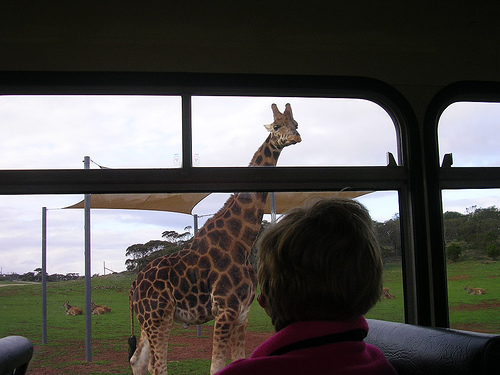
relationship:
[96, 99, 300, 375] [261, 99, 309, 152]
giraffe has head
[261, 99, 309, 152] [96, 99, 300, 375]
head of giraffe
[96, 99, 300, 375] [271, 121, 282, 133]
giraffe has eye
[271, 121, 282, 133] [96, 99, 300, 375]
eye of giraffe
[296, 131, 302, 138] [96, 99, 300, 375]
nose of giraffe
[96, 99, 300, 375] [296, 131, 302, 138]
giraffe has nose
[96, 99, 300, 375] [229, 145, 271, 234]
giraffe has neck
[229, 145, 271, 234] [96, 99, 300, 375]
neck of giraffe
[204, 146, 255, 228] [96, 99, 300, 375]
mane on giraffe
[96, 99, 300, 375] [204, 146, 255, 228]
giraffe has mane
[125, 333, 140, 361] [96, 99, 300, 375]
tail of giraffe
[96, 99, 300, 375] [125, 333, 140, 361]
giraffe has tail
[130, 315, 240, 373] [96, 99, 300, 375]
legs of giraffe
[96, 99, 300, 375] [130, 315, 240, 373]
giraffe has legs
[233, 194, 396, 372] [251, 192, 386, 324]
person has head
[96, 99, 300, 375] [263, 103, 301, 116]
giraffe has ears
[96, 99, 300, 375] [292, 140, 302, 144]
giraffe has mouth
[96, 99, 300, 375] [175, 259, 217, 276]
giraffe has spots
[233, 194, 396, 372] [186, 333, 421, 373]
person has jacket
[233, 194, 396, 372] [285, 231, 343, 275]
person has hair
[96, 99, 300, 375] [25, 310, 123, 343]
giraffe in grass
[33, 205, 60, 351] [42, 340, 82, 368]
pole in ground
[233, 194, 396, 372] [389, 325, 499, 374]
person in seat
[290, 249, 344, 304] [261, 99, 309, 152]
back of head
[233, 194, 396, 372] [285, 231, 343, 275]
woman has hair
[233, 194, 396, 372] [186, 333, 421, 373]
woman has jacket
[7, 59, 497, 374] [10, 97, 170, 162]
bus has window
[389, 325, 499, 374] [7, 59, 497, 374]
seat on bus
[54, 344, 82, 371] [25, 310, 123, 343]
patch on grass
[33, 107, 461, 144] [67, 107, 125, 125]
sky has clouds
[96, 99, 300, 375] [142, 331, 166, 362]
giraffe has stripes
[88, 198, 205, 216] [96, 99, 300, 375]
shade behind giraffe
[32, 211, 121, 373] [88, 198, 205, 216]
poles with caopies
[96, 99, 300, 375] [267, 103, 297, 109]
giraffe has hors